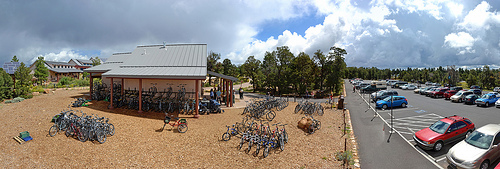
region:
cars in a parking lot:
[351, 69, 498, 166]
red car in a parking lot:
[411, 105, 473, 149]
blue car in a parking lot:
[373, 91, 408, 111]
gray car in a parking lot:
[446, 122, 498, 166]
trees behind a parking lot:
[349, 57, 499, 167]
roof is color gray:
[81, 37, 242, 118]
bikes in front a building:
[37, 78, 330, 165]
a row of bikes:
[216, 109, 291, 158]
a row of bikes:
[46, 107, 121, 148]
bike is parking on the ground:
[153, 105, 193, 141]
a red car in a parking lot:
[409, 113, 476, 154]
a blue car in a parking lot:
[377, 93, 409, 109]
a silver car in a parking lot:
[446, 121, 497, 167]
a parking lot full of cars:
[345, 77, 498, 167]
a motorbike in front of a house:
[158, 106, 188, 134]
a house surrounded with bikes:
[86, 42, 241, 115]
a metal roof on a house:
[87, 42, 214, 82]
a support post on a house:
[192, 78, 203, 118]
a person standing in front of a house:
[237, 83, 246, 100]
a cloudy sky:
[0, 0, 498, 67]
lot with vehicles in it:
[351, 79, 493, 149]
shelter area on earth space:
[82, 38, 242, 114]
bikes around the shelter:
[93, 79, 220, 116]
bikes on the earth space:
[52, 97, 114, 141]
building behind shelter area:
[21, 48, 91, 82]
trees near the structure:
[238, 43, 343, 88]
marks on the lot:
[393, 120, 423, 130]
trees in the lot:
[363, 66, 485, 82]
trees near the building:
[2, 68, 42, 98]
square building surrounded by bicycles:
[83, 36, 236, 121]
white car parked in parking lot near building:
[443, 120, 498, 167]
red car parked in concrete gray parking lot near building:
[410, 110, 480, 155]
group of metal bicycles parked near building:
[43, 104, 119, 142]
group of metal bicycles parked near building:
[218, 111, 289, 158]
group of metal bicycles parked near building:
[240, 92, 290, 122]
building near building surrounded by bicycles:
[23, 50, 108, 92]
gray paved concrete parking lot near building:
[341, 72, 498, 167]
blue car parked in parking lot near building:
[374, 93, 410, 110]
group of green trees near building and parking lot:
[243, 42, 348, 101]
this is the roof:
[112, 43, 204, 73]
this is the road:
[372, 140, 399, 158]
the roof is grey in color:
[127, 41, 202, 73]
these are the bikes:
[214, 107, 284, 157]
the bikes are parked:
[233, 81, 295, 150]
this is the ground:
[139, 136, 194, 167]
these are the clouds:
[386, 7, 442, 49]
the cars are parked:
[422, 107, 495, 164]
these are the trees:
[259, 47, 336, 83]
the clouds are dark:
[63, 0, 169, 45]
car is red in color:
[408, 108, 476, 150]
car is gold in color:
[451, 115, 496, 167]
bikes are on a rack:
[224, 108, 292, 155]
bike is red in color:
[157, 106, 192, 134]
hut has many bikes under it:
[84, 31, 247, 117]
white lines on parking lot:
[389, 105, 436, 134]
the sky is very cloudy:
[33, 14, 456, 59]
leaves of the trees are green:
[253, 28, 364, 99]